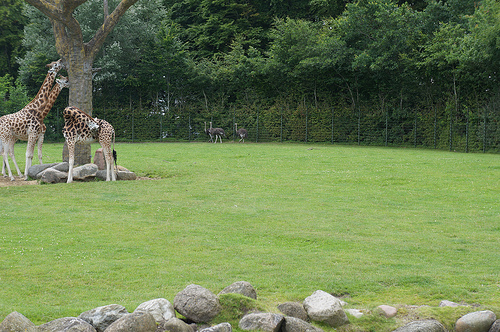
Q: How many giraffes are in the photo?
A: Three.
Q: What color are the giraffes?
A: Brown and tan.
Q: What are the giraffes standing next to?
A: Tree.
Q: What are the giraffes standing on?
A: Grass.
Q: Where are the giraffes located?
A: Green field.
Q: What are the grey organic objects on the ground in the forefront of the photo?
A: Rocks.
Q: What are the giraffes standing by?
A: A tree.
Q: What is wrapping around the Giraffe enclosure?
A: A chain-link fence.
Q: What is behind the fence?
A: A row of shrubs.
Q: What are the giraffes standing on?
A: Grass.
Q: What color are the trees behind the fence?
A: Green.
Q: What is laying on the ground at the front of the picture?
A: Stones.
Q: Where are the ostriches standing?
A: By the fence.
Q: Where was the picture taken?
A: In a zoo.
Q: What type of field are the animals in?
A: Green grassy area.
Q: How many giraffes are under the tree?
A: 3.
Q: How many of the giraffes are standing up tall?
A: 2.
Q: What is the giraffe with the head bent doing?
A: Cleaning himself.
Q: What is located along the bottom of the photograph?
A: Pile of rocks.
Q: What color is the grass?
A: Green.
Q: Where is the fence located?
A: Along the treeline.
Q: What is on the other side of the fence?
A: Bushes and trees.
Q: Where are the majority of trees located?
A: Along the fence.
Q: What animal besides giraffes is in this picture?
A: Ostrich.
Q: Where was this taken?
A: Zoo.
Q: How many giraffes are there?
A: Three.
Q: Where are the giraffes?
A: Next to the tree.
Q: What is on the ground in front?
A: Rocks.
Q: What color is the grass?
A: Green.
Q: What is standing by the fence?
A: Ostriches.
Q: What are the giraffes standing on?
A: Grass.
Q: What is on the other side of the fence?
A: Trees.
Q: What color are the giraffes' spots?
A: Brown.